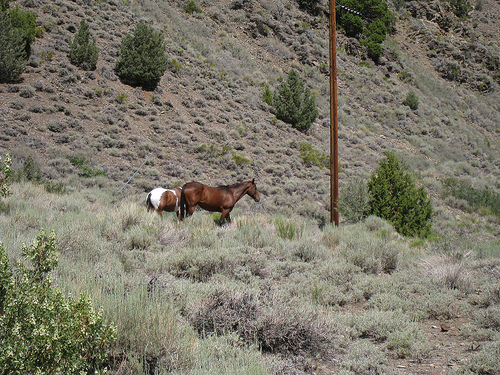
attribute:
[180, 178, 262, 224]
horse — brown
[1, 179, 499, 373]
grass — green, yellow, short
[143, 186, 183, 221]
horse — white, brow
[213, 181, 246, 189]
mane — black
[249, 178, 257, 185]
ear — black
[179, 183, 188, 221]
tail — black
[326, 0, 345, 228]
post — brown, wood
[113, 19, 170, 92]
bush — green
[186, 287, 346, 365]
bush — silver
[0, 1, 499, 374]
vegetation — desert, high